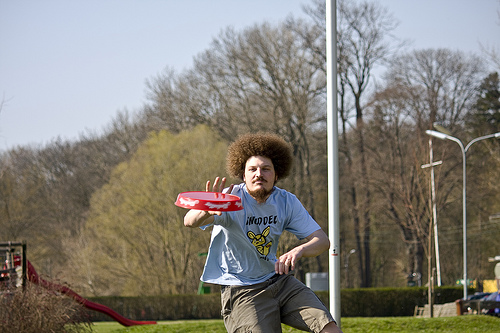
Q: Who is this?
A: A man.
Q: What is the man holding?
A: Frisbee.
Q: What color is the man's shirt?
A: Blue.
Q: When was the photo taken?
A: Daytime.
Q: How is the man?
A: In motion.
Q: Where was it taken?
A: In a park.